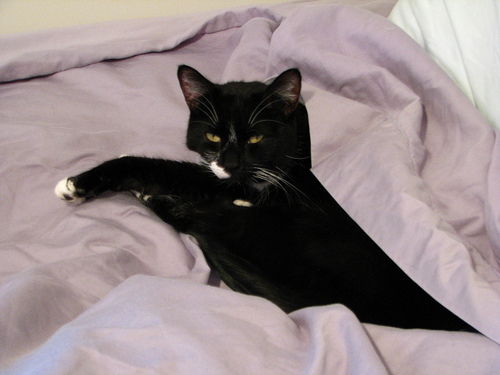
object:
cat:
[54, 62, 479, 334]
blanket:
[1, 3, 499, 373]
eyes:
[203, 130, 265, 144]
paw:
[56, 174, 94, 206]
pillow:
[387, 0, 499, 132]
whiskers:
[248, 160, 321, 213]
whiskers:
[181, 86, 299, 127]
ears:
[175, 64, 303, 103]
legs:
[54, 154, 221, 228]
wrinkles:
[51, 208, 142, 278]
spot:
[209, 160, 231, 179]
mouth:
[215, 169, 256, 186]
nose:
[223, 163, 244, 174]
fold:
[0, 0, 500, 375]